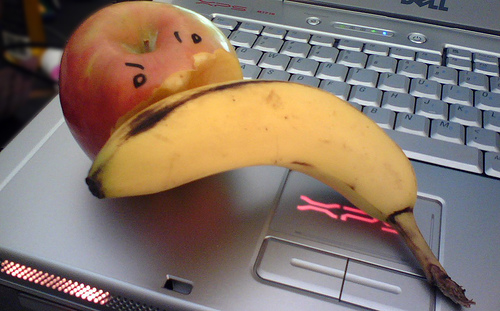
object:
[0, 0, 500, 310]
laptop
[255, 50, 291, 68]
black letters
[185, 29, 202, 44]
eyes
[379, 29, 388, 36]
light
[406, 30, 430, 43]
button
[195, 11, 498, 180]
keyboard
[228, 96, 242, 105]
spot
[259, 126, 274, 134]
spot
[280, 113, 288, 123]
spot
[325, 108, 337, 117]
spot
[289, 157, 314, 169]
spot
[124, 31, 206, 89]
marks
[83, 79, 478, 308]
banana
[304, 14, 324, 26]
power buttons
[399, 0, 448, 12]
dell laptop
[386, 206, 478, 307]
banana stem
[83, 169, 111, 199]
banana end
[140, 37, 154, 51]
apple stem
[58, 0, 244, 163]
apple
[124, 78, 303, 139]
banana marks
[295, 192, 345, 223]
pink letters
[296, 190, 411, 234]
xps on trackpad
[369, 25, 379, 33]
light on laptop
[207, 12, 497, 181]
silver keys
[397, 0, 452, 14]
dell logo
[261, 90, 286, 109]
banana spots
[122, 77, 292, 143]
brown streak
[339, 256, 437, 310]
mouse buttons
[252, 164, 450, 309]
touch pad